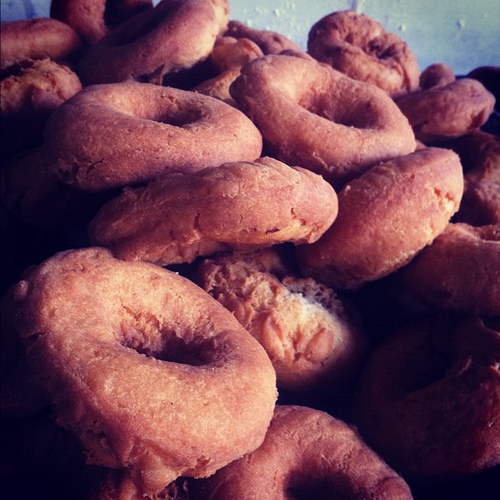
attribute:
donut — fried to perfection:
[59, 73, 254, 175]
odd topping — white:
[281, 272, 353, 353]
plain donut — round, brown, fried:
[230, 50, 417, 184]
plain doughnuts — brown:
[58, 76, 348, 268]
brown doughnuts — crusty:
[229, 52, 465, 281]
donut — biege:
[21, 233, 291, 471]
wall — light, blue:
[233, 3, 491, 74]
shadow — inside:
[156, 336, 210, 374]